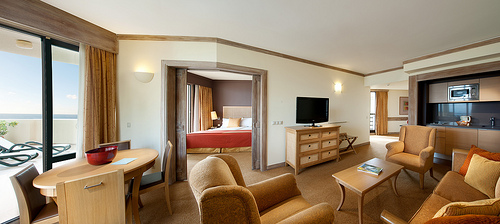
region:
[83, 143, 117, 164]
The burgundy bowl on the table.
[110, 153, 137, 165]
The white paper on the table.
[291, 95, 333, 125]
The black flat screen t.v.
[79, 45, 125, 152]
The curtain on the open window showing the back deck.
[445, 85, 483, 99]
The microwave above the sink area.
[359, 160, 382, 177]
The magazine on the center table.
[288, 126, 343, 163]
The dresser the t.v. is on top of.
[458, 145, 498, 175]
The orange pillow on the sofa.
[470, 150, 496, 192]
The beige pillow in front of the orange pillow on the sofa.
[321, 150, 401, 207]
The center table in the living room.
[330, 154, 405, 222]
a light wooden chair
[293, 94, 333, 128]
a flat screen television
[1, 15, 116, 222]
a large glass sliding door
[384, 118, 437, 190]
a small coach chair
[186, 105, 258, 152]
a large bed with orange cover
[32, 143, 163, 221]
a round wooden table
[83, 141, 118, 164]
a large red bowl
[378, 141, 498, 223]
a light brown coach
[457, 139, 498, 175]
an orange square pillow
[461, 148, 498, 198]
a square beige pillow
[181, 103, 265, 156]
bed with red sheets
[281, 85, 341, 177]
television set on clothes drawer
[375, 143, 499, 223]
couch with pillows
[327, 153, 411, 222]
magazine on the table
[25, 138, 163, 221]
red bowl on the table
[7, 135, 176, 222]
four beige chairs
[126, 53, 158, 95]
light fixture on the wall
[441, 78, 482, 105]
microwave in wall recess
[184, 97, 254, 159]
beige pillow on the bed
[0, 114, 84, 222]
two chairs in patio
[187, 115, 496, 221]
Room filled with furniture.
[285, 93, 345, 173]
Dresser holding large television.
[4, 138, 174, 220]
A table for four by glass sliding door.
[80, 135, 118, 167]
Red bowl sitting on top of table.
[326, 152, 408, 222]
Coffee table in center of seating area.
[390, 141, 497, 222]
Love seat in front of coffee table.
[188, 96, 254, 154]
A bed inside bedroom.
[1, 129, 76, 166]
Two chaise lounge chairs on patio.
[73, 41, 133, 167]
Brown drapes at glass sliding door.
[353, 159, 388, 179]
Book laying on coffee table.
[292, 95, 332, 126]
small flat screen televisio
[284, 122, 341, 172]
brown and beige chest of drawers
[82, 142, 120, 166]
red bowl on oval table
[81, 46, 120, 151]
brown curtain for picture window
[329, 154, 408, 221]
small brown coffee table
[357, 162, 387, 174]
book on coffee table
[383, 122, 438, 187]
brown cushioned chair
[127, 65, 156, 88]
wall light in livingroom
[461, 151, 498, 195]
brown pillow a couch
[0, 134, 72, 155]
lounge chair on a patio